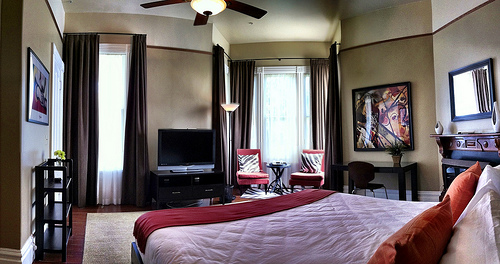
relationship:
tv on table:
[160, 129, 217, 176] [153, 172, 226, 205]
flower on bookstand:
[55, 150, 67, 164] [36, 159, 76, 262]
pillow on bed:
[367, 196, 454, 263] [134, 162, 498, 262]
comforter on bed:
[136, 189, 441, 263] [134, 162, 498, 262]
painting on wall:
[353, 80, 416, 149] [0, 0, 498, 250]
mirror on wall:
[450, 62, 496, 121] [0, 0, 498, 250]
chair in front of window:
[235, 147, 269, 191] [260, 72, 304, 164]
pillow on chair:
[239, 155, 262, 173] [235, 147, 269, 191]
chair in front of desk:
[349, 162, 390, 198] [332, 163, 419, 200]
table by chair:
[267, 163, 289, 193] [235, 147, 269, 191]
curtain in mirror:
[473, 64, 493, 113] [450, 62, 496, 121]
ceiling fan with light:
[141, 1, 269, 26] [191, 1, 226, 17]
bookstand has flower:
[36, 159, 76, 262] [55, 150, 67, 164]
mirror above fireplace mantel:
[450, 62, 496, 121] [435, 134, 499, 203]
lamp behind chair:
[222, 102, 241, 202] [235, 147, 269, 191]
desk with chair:
[332, 163, 419, 200] [349, 162, 390, 198]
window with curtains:
[260, 72, 304, 164] [232, 59, 332, 187]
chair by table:
[235, 147, 269, 191] [267, 163, 289, 193]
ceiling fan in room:
[141, 1, 269, 26] [0, 0, 499, 263]